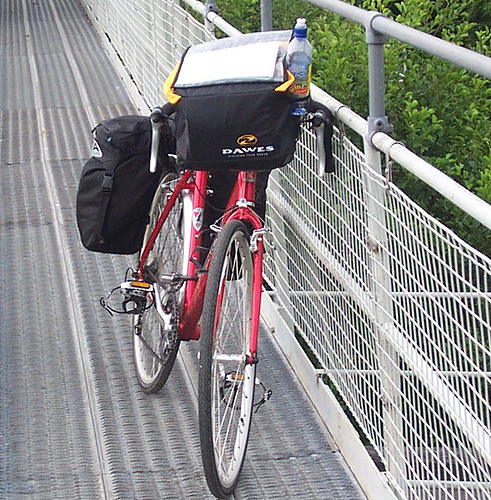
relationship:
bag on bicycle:
[70, 112, 175, 255] [96, 92, 343, 500]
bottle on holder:
[284, 17, 312, 117] [278, 64, 313, 96]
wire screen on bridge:
[279, 159, 488, 381] [5, 71, 459, 414]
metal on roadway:
[4, 2, 369, 497] [2, 4, 367, 498]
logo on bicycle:
[189, 203, 205, 232] [96, 92, 343, 500]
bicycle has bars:
[101, 94, 339, 496] [146, 101, 178, 175]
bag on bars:
[170, 27, 299, 171] [146, 101, 178, 175]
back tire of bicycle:
[129, 168, 195, 395] [134, 169, 272, 497]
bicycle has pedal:
[96, 92, 343, 500] [219, 369, 273, 412]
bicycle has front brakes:
[96, 92, 343, 500] [211, 209, 272, 255]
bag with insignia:
[162, 38, 308, 182] [235, 131, 260, 148]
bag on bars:
[162, 38, 308, 182] [143, 99, 333, 178]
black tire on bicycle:
[197, 217, 260, 497] [101, 94, 339, 496]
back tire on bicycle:
[129, 168, 195, 395] [101, 94, 339, 496]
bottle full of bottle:
[283, 16, 312, 117] [284, 17, 312, 117]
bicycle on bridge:
[96, 92, 343, 500] [0, 0, 488, 497]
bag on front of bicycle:
[170, 27, 299, 171] [96, 92, 343, 500]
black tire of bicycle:
[193, 224, 260, 498] [96, 92, 343, 500]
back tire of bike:
[129, 168, 195, 395] [77, 26, 341, 488]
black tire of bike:
[193, 224, 260, 498] [77, 26, 341, 488]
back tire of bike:
[129, 172, 190, 388] [65, 61, 312, 492]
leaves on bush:
[218, 0, 489, 253] [194, 0, 490, 262]